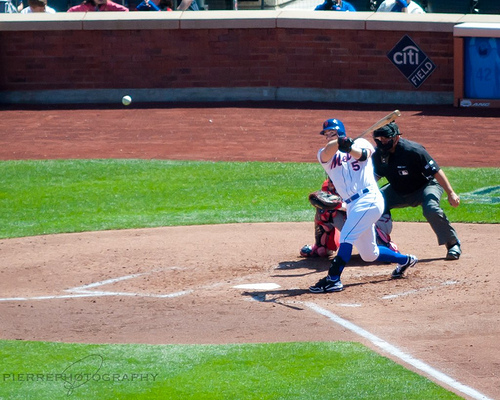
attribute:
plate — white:
[236, 272, 286, 321]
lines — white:
[114, 274, 468, 399]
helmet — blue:
[305, 117, 341, 140]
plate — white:
[234, 263, 283, 297]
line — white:
[319, 308, 488, 398]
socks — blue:
[328, 224, 411, 276]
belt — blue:
[339, 194, 397, 214]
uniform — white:
[314, 139, 412, 273]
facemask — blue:
[356, 124, 405, 156]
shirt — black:
[374, 115, 448, 200]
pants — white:
[341, 183, 395, 270]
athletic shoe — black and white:
[309, 276, 342, 294]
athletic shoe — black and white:
[389, 253, 419, 280]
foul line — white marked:
[2, 282, 87, 306]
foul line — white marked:
[307, 295, 471, 391]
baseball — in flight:
[120, 90, 134, 108]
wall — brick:
[1, 13, 483, 118]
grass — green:
[3, 338, 462, 397]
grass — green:
[2, 155, 481, 254]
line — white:
[1, 268, 205, 313]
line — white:
[301, 295, 484, 397]